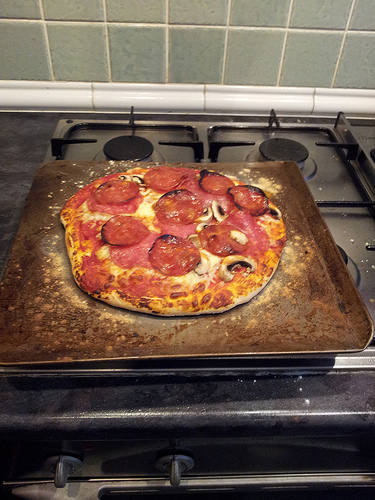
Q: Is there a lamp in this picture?
A: No, there are no lamps.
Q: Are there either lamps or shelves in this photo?
A: No, there are no lamps or shelves.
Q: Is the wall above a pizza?
A: Yes, the wall is above a pizza.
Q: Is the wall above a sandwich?
A: No, the wall is above a pizza.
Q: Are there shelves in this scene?
A: No, there are no shelves.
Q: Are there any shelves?
A: No, there are no shelves.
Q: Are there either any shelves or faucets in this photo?
A: No, there are no shelves or faucets.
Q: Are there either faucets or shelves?
A: No, there are no shelves or faucets.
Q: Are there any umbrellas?
A: No, there are no umbrellas.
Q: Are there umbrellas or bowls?
A: No, there are no umbrellas or bowls.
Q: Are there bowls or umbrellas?
A: No, there are no umbrellas or bowls.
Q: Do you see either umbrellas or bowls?
A: No, there are no umbrellas or bowls.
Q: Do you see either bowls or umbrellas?
A: No, there are no umbrellas or bowls.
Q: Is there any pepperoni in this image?
A: Yes, there is pepperoni.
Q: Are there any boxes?
A: No, there are no boxes.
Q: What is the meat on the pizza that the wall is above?
A: The meat is pepperoni.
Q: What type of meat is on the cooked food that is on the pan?
A: The meat is pepperoni.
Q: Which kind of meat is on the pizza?
A: The meat is pepperoni.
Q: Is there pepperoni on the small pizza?
A: Yes, there is pepperoni on the pizza.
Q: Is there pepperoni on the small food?
A: Yes, there is pepperoni on the pizza.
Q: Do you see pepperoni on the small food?
A: Yes, there is pepperoni on the pizza.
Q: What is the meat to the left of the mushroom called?
A: The meat is pepperoni.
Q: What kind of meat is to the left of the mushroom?
A: The meat is pepperoni.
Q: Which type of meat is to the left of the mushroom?
A: The meat is pepperoni.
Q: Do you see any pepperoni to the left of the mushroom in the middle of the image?
A: Yes, there is pepperoni to the left of the mushroom.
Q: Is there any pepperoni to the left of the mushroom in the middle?
A: Yes, there is pepperoni to the left of the mushroom.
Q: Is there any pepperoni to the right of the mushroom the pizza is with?
A: No, the pepperoni is to the left of the mushroom.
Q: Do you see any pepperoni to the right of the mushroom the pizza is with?
A: No, the pepperoni is to the left of the mushroom.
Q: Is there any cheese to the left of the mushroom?
A: No, there is pepperoni to the left of the mushroom.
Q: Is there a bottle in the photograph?
A: No, there are no bottles.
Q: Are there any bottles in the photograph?
A: No, there are no bottles.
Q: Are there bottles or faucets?
A: No, there are no bottles or faucets.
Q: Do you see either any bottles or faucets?
A: No, there are no bottles or faucets.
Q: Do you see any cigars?
A: No, there are no cigars.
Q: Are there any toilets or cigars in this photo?
A: No, there are no cigars or toilets.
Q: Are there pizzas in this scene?
A: Yes, there is a pizza.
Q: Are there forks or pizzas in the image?
A: Yes, there is a pizza.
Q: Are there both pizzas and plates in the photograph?
A: No, there is a pizza but no plates.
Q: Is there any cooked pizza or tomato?
A: Yes, there is a cooked pizza.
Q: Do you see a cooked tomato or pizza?
A: Yes, there is a cooked pizza.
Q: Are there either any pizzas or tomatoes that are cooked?
A: Yes, the pizza is cooked.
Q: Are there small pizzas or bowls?
A: Yes, there is a small pizza.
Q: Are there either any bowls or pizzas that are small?
A: Yes, the pizza is small.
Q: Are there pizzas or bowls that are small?
A: Yes, the pizza is small.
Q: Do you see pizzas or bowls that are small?
A: Yes, the pizza is small.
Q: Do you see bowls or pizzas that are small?
A: Yes, the pizza is small.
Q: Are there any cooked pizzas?
A: Yes, there is a cooked pizza.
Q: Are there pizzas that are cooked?
A: Yes, there is a pizza that is cooked.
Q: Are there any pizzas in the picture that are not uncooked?
A: Yes, there is an cooked pizza.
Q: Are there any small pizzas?
A: Yes, there is a small pizza.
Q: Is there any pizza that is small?
A: Yes, there is a pizza that is small.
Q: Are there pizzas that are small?
A: Yes, there is a pizza that is small.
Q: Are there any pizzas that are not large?
A: Yes, there is a small pizza.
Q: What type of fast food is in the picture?
A: The fast food is a pizza.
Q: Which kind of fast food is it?
A: The food is a pizza.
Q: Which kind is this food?
A: This is a pizza.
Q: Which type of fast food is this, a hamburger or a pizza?
A: This is a pizza.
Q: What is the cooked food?
A: The food is a pizza.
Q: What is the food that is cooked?
A: The food is a pizza.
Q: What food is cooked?
A: The food is a pizza.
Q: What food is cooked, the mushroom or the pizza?
A: The pizza is cooked.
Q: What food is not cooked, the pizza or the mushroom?
A: The mushroom is not cooked.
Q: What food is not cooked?
A: The food is a mushroom.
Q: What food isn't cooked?
A: The food is a mushroom.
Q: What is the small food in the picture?
A: The food is a pizza.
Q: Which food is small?
A: The food is a pizza.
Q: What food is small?
A: The food is a pizza.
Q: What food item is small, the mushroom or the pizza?
A: The pizza is small.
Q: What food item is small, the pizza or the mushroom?
A: The pizza is small.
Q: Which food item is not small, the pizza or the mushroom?
A: The mushroom is not small.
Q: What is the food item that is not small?
A: The food item is a mushroom.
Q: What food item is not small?
A: The food item is a mushroom.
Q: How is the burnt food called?
A: The food is a pizza.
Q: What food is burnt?
A: The food is a pizza.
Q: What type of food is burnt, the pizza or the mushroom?
A: The pizza is burnt.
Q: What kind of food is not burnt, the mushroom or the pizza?
A: The mushroom is not burnt.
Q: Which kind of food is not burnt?
A: The food is a mushroom.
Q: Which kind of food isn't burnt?
A: The food is a mushroom.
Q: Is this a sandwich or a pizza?
A: This is a pizza.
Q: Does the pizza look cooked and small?
A: Yes, the pizza is cooked and small.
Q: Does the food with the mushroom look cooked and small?
A: Yes, the pizza is cooked and small.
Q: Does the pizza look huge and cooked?
A: No, the pizza is cooked but small.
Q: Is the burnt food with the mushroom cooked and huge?
A: No, the pizza is cooked but small.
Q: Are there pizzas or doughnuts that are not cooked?
A: No, there is a pizza but it is cooked.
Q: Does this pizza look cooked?
A: Yes, the pizza is cooked.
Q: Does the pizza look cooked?
A: Yes, the pizza is cooked.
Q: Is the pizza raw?
A: No, the pizza is cooked.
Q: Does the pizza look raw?
A: No, the pizza is cooked.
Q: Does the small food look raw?
A: No, the pizza is cooked.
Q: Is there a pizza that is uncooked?
A: No, there is a pizza but it is cooked.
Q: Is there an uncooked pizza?
A: No, there is a pizza but it is cooked.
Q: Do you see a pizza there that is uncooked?
A: No, there is a pizza but it is cooked.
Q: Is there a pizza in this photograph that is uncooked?
A: No, there is a pizza but it is cooked.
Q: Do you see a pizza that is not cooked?
A: No, there is a pizza but it is cooked.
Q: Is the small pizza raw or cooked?
A: The pizza is cooked.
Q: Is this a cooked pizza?
A: Yes, this is a cooked pizza.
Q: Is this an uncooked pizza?
A: No, this is a cooked pizza.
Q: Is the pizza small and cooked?
A: Yes, the pizza is small and cooked.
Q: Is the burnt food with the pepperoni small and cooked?
A: Yes, the pizza is small and cooked.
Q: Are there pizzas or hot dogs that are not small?
A: No, there is a pizza but it is small.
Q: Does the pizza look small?
A: Yes, the pizza is small.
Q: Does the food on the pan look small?
A: Yes, the pizza is small.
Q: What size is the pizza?
A: The pizza is small.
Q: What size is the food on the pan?
A: The pizza is small.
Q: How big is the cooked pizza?
A: The pizza is small.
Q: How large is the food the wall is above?
A: The pizza is small.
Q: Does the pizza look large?
A: No, the pizza is small.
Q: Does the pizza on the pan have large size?
A: No, the pizza is small.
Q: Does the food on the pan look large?
A: No, the pizza is small.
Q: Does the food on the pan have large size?
A: No, the pizza is small.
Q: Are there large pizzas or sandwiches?
A: No, there is a pizza but it is small.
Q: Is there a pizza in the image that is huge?
A: No, there is a pizza but it is small.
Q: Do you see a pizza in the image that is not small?
A: No, there is a pizza but it is small.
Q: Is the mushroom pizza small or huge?
A: The pizza is small.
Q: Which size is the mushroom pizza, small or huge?
A: The pizza is small.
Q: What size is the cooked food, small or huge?
A: The pizza is small.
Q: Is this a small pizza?
A: Yes, this is a small pizza.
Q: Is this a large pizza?
A: No, this is a small pizza.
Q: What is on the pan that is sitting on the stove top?
A: The pizza is on the pan.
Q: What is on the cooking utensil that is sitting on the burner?
A: The pizza is on the pan.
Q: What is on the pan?
A: The pizza is on the pan.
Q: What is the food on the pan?
A: The food is a pizza.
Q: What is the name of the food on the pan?
A: The food is a pizza.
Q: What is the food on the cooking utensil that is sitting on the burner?
A: The food is a pizza.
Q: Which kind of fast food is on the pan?
A: The food is a pizza.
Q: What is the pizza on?
A: The pizza is on the pan.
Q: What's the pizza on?
A: The pizza is on the pan.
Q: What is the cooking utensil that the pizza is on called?
A: The cooking utensil is a pan.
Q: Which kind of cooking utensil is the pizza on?
A: The pizza is on the pan.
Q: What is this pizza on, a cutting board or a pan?
A: The pizza is on a pan.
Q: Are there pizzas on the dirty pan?
A: Yes, there is a pizza on the pan.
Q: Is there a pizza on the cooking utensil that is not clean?
A: Yes, there is a pizza on the pan.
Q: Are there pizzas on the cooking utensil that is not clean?
A: Yes, there is a pizza on the pan.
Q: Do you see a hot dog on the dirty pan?
A: No, there is a pizza on the pan.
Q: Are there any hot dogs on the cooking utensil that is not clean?
A: No, there is a pizza on the pan.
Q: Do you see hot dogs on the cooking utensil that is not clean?
A: No, there is a pizza on the pan.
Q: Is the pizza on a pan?
A: Yes, the pizza is on a pan.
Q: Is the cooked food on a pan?
A: Yes, the pizza is on a pan.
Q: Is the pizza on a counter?
A: No, the pizza is on a pan.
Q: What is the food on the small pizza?
A: The food is a mushroom.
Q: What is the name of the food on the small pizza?
A: The food is a mushroom.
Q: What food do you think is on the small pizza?
A: The food is a mushroom.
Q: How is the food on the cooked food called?
A: The food is a mushroom.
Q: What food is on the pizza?
A: The food is a mushroom.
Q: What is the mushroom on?
A: The mushroom is on the pizza.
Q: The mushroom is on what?
A: The mushroom is on the pizza.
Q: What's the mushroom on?
A: The mushroom is on the pizza.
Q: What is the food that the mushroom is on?
A: The food is a pizza.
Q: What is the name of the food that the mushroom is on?
A: The food is a pizza.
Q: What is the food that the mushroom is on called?
A: The food is a pizza.